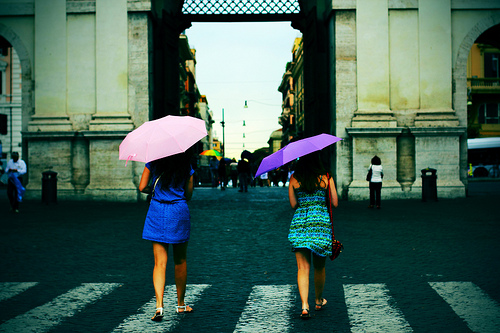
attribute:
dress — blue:
[141, 151, 194, 242]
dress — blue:
[287, 185, 333, 258]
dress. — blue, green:
[286, 183, 346, 255]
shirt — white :
[366, 155, 384, 208]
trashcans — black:
[420, 165, 440, 203]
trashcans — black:
[38, 170, 61, 205]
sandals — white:
[151, 302, 196, 319]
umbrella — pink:
[117, 113, 207, 165]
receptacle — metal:
[419, 165, 441, 203]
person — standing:
[276, 149, 345, 314]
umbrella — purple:
[254, 123, 339, 181]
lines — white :
[5, 275, 482, 331]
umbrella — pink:
[115, 112, 213, 167]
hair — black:
[143, 148, 198, 194]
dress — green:
[280, 166, 339, 266]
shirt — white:
[7, 158, 22, 169]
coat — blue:
[4, 166, 32, 208]